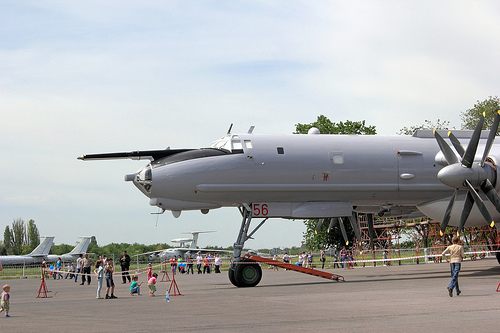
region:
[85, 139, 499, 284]
airplane on the ground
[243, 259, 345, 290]
red ladder to the plane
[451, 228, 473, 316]
person walking toward the plane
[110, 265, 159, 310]
children crouching to see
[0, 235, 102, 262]
two planes in the background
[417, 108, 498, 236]
propeller wings on the plane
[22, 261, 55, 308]
red sign in front of plane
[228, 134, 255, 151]
two windows of the cockpit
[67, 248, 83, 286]
man walking away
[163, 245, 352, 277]
spectators watching the children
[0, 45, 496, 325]
The people are walking around an air show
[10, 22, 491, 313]
The planes are being publicly displayed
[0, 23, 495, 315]
People are examining the airplane closely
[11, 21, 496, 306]
The planes were designed for combat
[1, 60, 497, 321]
The planes are on an airstrip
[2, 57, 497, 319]
Planes are being shown to the public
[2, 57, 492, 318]
The planes belong to the military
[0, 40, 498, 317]
People are walking all around the planes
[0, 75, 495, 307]
The planes are designed to carry armaments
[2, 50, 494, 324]
Planes are displayed at an air base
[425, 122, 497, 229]
propellers on the wing of a plance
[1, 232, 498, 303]
people at an air show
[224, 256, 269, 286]
wheels on a plane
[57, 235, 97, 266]
the tail of a distant plane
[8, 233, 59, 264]
the tail of distant plane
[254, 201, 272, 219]
red numbers on a silver plane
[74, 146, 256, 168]
a black antenna on a gray plane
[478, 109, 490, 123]
the yellow tip on a propeller blade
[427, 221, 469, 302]
a man wearing bluejeans running under the plane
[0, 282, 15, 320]
a baby walking on the asphalt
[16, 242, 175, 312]
people watching the plane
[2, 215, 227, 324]
people watching the plane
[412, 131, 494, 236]
the two gray propellers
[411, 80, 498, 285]
the two gray propellers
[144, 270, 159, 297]
girl wearing pink shirt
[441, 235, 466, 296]
person wearing blue jeans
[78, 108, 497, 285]
plane parked on tarmac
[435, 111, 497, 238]
propellerl on silver plane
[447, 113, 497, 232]
propeller on silver plane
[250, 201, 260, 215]
red number on silver plane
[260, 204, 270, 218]
red number on silver plane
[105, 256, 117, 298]
person looking at plane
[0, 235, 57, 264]
plane is next to plane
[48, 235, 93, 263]
plane is next to plane